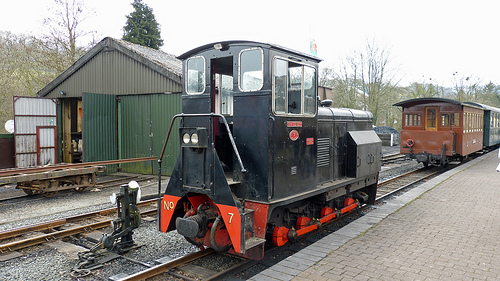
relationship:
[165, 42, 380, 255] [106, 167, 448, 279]
train on track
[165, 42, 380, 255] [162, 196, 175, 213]
train has letters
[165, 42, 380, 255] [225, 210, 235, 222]
train has numbers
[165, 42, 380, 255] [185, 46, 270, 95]
train has windows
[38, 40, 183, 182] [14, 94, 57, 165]
building has door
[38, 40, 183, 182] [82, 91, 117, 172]
building has door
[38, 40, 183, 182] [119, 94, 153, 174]
building has door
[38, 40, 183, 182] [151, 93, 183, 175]
building has door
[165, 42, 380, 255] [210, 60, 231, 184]
train has door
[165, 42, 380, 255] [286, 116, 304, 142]
train has letters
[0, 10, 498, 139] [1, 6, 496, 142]
trees in background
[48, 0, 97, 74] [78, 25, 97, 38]
tree has no leaves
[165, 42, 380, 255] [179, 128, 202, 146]
train has lights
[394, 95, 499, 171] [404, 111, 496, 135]
traincar has windows